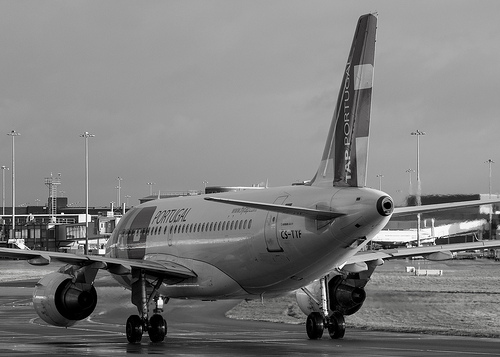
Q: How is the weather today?
A: It is cloudy.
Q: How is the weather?
A: It is cloudy.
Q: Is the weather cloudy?
A: Yes, it is cloudy.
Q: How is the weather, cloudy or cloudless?
A: It is cloudy.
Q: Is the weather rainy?
A: No, it is cloudy.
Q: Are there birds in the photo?
A: No, there are no birds.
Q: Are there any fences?
A: No, there are no fences.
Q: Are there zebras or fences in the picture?
A: No, there are no fences or zebras.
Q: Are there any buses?
A: No, there are no buses.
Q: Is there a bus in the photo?
A: No, there are no buses.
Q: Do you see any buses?
A: No, there are no buses.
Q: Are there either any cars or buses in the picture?
A: No, there are no buses or cars.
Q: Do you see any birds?
A: No, there are no birds.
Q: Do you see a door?
A: Yes, there is a door.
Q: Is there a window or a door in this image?
A: Yes, there is a door.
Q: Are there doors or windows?
A: Yes, there is a door.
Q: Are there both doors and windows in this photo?
A: Yes, there are both a door and a window.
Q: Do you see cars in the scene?
A: No, there are no cars.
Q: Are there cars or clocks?
A: No, there are no cars or clocks.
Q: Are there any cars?
A: No, there are no cars.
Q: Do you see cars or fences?
A: No, there are no cars or fences.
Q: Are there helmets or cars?
A: No, there are no cars or helmets.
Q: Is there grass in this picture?
A: Yes, there is grass.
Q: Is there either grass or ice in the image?
A: Yes, there is grass.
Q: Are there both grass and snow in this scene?
A: No, there is grass but no snow.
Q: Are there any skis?
A: No, there are no skis.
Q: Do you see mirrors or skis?
A: No, there are no skis or mirrors.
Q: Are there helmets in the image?
A: No, there are no helmets.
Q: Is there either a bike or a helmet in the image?
A: No, there are no helmets or bikes.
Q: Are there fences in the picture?
A: No, there are no fences.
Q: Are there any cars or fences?
A: No, there are no fences or cars.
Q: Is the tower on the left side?
A: Yes, the tower is on the left of the image.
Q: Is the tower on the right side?
A: No, the tower is on the left of the image.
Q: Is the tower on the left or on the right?
A: The tower is on the left of the image.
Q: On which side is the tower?
A: The tower is on the left of the image.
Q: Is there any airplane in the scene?
A: Yes, there is an airplane.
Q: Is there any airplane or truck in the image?
A: Yes, there is an airplane.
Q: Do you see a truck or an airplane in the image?
A: Yes, there is an airplane.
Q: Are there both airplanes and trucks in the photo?
A: No, there is an airplane but no trucks.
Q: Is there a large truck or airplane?
A: Yes, there is a large airplane.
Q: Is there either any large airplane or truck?
A: Yes, there is a large airplane.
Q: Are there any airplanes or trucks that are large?
A: Yes, the airplane is large.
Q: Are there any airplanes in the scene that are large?
A: Yes, there is a large airplane.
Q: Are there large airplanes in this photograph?
A: Yes, there is a large airplane.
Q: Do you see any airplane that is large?
A: Yes, there is an airplane that is large.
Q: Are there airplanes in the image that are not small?
A: Yes, there is a large airplane.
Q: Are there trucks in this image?
A: No, there are no trucks.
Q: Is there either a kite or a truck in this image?
A: No, there are no trucks or kites.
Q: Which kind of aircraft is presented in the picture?
A: The aircraft is an airplane.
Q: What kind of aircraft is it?
A: The aircraft is an airplane.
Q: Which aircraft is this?
A: That is an airplane.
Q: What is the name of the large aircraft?
A: The aircraft is an airplane.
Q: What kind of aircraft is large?
A: The aircraft is an airplane.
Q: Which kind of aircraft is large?
A: The aircraft is an airplane.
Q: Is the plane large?
A: Yes, the plane is large.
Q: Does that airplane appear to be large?
A: Yes, the airplane is large.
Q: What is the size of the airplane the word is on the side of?
A: The plane is large.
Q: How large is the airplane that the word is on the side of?
A: The plane is large.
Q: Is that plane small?
A: No, the plane is large.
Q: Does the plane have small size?
A: No, the plane is large.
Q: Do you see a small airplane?
A: No, there is an airplane but it is large.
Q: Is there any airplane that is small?
A: No, there is an airplane but it is large.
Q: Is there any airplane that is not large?
A: No, there is an airplane but it is large.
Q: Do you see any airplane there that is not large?
A: No, there is an airplane but it is large.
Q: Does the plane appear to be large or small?
A: The plane is large.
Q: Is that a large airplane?
A: Yes, that is a large airplane.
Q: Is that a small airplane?
A: No, that is a large airplane.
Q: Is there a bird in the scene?
A: No, there are no birds.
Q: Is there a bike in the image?
A: No, there are no bikes.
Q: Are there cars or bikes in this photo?
A: No, there are no bikes or cars.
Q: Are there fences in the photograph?
A: No, there are no fences.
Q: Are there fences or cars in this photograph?
A: No, there are no fences or cars.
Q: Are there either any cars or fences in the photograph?
A: No, there are no fences or cars.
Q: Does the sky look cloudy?
A: Yes, the sky is cloudy.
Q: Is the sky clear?
A: No, the sky is cloudy.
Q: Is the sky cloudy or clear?
A: The sky is cloudy.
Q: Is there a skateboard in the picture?
A: No, there are no skateboards.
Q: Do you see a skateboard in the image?
A: No, there are no skateboards.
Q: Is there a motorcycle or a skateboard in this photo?
A: No, there are no skateboards or motorcycles.